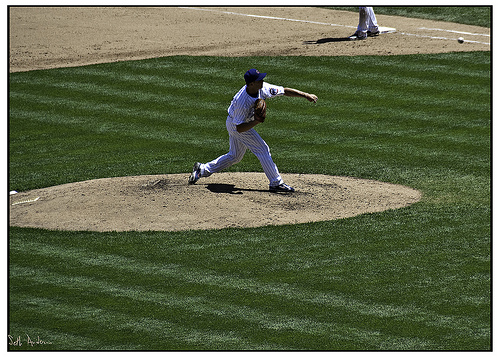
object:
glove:
[252, 93, 272, 126]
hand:
[307, 92, 321, 101]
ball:
[455, 35, 464, 44]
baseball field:
[9, 5, 489, 351]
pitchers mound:
[13, 168, 424, 233]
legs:
[343, 5, 369, 40]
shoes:
[187, 159, 212, 185]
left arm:
[268, 83, 325, 115]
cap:
[243, 67, 267, 83]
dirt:
[102, 168, 283, 207]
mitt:
[250, 96, 273, 121]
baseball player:
[188, 67, 318, 195]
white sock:
[198, 117, 283, 187]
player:
[343, 6, 382, 39]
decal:
[268, 86, 278, 96]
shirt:
[226, 79, 285, 126]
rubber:
[140, 175, 163, 189]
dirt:
[68, 10, 171, 66]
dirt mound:
[11, 167, 420, 232]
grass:
[8, 57, 488, 344]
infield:
[0, 0, 488, 349]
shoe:
[265, 177, 297, 191]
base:
[373, 24, 396, 34]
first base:
[372, 22, 396, 34]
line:
[184, 0, 447, 40]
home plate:
[356, 22, 393, 38]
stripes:
[224, 118, 283, 185]